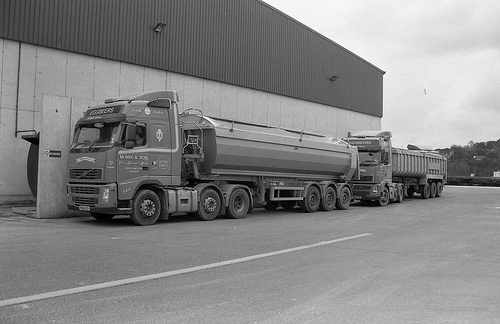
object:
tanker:
[177, 107, 361, 183]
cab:
[346, 131, 393, 183]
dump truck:
[346, 131, 449, 207]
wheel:
[300, 182, 322, 213]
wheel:
[422, 183, 429, 198]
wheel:
[229, 188, 251, 218]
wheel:
[430, 181, 439, 199]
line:
[0, 233, 367, 307]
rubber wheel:
[396, 182, 405, 203]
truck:
[336, 129, 449, 205]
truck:
[65, 88, 360, 225]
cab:
[63, 91, 183, 186]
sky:
[261, 0, 499, 150]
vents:
[67, 168, 102, 179]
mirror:
[381, 153, 390, 163]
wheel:
[129, 186, 162, 226]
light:
[330, 74, 338, 81]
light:
[152, 21, 165, 32]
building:
[0, 0, 386, 208]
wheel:
[322, 184, 337, 213]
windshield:
[70, 121, 123, 143]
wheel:
[377, 186, 392, 206]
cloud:
[262, 0, 499, 150]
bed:
[394, 172, 445, 186]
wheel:
[197, 185, 220, 223]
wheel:
[337, 184, 352, 212]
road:
[0, 185, 499, 323]